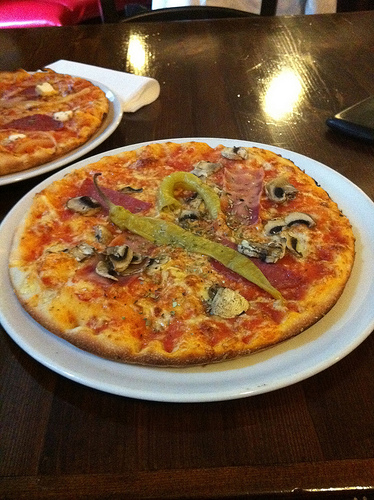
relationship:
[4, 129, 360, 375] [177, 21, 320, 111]
pizza on top of table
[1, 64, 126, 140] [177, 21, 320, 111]
pizza on top of table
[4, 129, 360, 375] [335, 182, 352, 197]
pizza on top of plate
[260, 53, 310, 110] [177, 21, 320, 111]
light reflecting off table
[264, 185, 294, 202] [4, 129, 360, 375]
mushroom on top of pizza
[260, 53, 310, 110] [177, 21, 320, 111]
light reflecting on table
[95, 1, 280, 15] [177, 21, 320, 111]
chair at a table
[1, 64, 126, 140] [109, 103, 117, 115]
pizza on top of plate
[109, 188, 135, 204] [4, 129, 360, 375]
pepperoni on top of pizza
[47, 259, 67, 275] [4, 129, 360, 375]
cheese across a pizza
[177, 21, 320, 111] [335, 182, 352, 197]
table beneath plate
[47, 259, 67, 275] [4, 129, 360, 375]
cheese across pizza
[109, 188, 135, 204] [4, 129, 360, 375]
pepperoni on top of a pizza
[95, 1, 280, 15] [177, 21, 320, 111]
chair at table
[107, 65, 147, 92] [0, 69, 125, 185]
napkin under plate